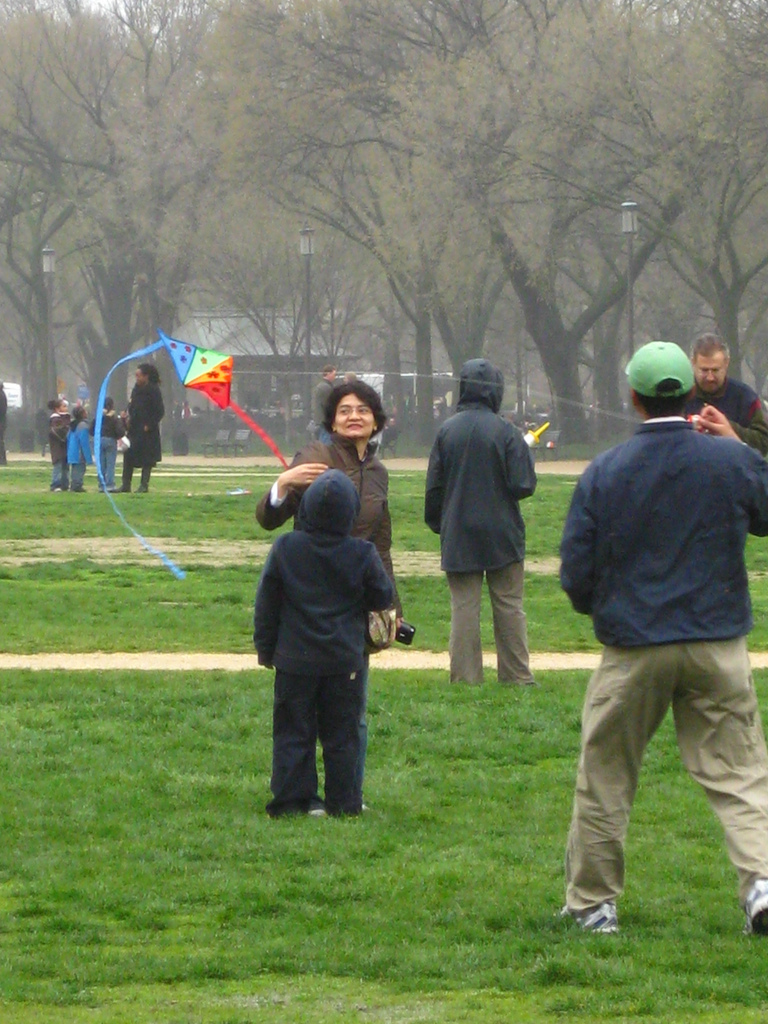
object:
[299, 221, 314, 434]
light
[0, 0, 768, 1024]
park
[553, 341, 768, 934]
man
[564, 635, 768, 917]
pant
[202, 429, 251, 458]
bench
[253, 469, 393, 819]
child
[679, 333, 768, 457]
man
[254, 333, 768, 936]
people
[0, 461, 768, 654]
grass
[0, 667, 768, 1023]
grass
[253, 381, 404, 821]
people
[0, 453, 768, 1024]
ground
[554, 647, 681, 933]
leg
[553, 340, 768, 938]
person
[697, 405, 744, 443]
head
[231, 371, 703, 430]
string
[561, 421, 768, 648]
jacket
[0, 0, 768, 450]
trees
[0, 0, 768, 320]
leaves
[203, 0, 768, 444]
tree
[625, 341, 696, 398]
green cap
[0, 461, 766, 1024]
grass field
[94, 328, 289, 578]
kite